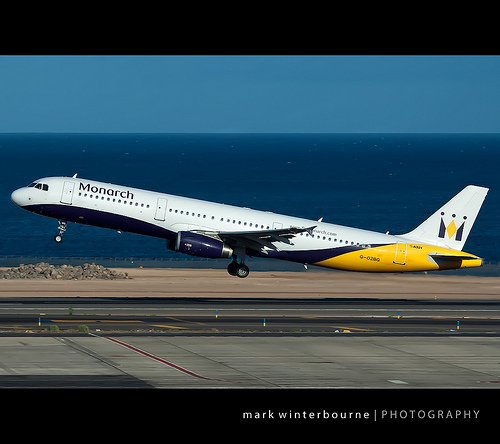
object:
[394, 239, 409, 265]
door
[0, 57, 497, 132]
sky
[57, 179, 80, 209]
door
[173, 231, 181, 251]
plane turbine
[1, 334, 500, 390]
runway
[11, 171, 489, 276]
plane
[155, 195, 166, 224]
door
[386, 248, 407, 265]
yellow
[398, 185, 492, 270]
tail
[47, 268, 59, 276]
rocks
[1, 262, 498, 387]
ground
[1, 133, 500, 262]
ocean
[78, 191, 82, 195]
windows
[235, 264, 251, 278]
wheels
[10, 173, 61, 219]
front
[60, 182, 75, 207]
door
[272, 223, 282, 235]
door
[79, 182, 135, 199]
logo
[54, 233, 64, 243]
tire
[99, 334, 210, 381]
line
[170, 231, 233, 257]
engine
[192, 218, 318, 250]
wing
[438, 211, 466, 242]
logo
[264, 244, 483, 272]
design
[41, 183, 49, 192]
cockpit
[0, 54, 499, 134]
clear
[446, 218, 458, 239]
diamond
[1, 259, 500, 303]
beach